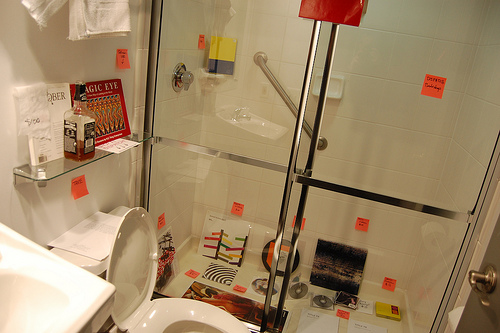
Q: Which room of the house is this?
A: It is a bathroom.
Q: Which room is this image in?
A: It is at the bathroom.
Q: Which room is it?
A: It is a bathroom.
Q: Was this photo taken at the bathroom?
A: Yes, it was taken in the bathroom.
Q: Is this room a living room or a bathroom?
A: It is a bathroom.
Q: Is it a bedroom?
A: No, it is a bathroom.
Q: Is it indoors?
A: Yes, it is indoors.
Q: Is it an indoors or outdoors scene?
A: It is indoors.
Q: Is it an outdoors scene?
A: No, it is indoors.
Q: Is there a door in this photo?
A: Yes, there is a door.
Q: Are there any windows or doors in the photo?
A: Yes, there is a door.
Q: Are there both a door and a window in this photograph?
A: No, there is a door but no windows.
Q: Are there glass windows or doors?
A: Yes, there is a glass door.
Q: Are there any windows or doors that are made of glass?
A: Yes, the door is made of glass.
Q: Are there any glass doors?
A: Yes, there is a door that is made of glass.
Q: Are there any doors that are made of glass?
A: Yes, there is a door that is made of glass.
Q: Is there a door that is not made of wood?
A: Yes, there is a door that is made of glass.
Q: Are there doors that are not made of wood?
A: Yes, there is a door that is made of glass.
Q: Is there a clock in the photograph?
A: No, there are no clocks.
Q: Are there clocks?
A: No, there are no clocks.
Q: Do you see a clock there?
A: No, there are no clocks.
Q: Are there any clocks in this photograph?
A: No, there are no clocks.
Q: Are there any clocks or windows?
A: No, there are no clocks or windows.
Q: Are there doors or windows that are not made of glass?
A: No, there is a door but it is made of glass.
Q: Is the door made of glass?
A: Yes, the door is made of glass.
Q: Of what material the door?
A: The door is made of glass.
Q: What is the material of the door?
A: The door is made of glass.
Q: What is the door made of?
A: The door is made of glass.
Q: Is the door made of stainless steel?
A: No, the door is made of glass.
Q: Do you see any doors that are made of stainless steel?
A: No, there is a door but it is made of glass.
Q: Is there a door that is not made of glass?
A: No, there is a door but it is made of glass.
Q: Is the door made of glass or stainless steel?
A: The door is made of glass.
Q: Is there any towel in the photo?
A: Yes, there is a towel.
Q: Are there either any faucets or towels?
A: Yes, there is a towel.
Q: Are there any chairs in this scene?
A: No, there are no chairs.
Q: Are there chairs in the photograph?
A: No, there are no chairs.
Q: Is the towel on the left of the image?
A: Yes, the towel is on the left of the image.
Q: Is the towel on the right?
A: No, the towel is on the left of the image.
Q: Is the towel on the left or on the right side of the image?
A: The towel is on the left of the image.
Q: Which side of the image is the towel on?
A: The towel is on the left of the image.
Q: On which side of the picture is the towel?
A: The towel is on the left of the image.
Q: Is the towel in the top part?
A: Yes, the towel is in the top of the image.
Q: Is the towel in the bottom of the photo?
A: No, the towel is in the top of the image.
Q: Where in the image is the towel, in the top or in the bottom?
A: The towel is in the top of the image.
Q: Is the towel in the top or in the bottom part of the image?
A: The towel is in the top of the image.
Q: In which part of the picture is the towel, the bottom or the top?
A: The towel is in the top of the image.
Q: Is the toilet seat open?
A: Yes, the toilet seat is open.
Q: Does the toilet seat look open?
A: Yes, the toilet seat is open.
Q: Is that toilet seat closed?
A: No, the toilet seat is open.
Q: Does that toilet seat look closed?
A: No, the toilet seat is open.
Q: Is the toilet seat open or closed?
A: The toilet seat is open.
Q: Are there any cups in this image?
A: No, there are no cups.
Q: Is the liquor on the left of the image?
A: Yes, the liquor is on the left of the image.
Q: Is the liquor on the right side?
A: No, the liquor is on the left of the image.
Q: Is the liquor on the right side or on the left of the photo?
A: The liquor is on the left of the image.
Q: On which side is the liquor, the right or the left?
A: The liquor is on the left of the image.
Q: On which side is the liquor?
A: The liquor is on the left of the image.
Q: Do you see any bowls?
A: No, there are no bowls.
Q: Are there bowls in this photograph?
A: No, there are no bowls.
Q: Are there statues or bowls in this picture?
A: No, there are no bowls or statues.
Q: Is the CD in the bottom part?
A: Yes, the CD is in the bottom of the image.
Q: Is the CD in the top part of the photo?
A: No, the CD is in the bottom of the image.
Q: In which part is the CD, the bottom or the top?
A: The CD is in the bottom of the image.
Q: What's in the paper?
A: The CD is in the paper.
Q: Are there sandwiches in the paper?
A: No, there is a CD in the paper.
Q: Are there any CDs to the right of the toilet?
A: Yes, there is a CD to the right of the toilet.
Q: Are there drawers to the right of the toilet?
A: No, there is a CD to the right of the toilet.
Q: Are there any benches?
A: No, there are no benches.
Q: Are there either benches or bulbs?
A: No, there are no benches or bulbs.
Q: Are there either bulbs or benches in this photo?
A: No, there are no benches or bulbs.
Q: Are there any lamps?
A: No, there are no lamps.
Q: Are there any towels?
A: Yes, there is a towel.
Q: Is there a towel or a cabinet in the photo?
A: Yes, there is a towel.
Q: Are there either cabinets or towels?
A: Yes, there is a towel.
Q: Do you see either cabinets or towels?
A: Yes, there is a towel.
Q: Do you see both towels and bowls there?
A: No, there is a towel but no bowls.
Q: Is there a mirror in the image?
A: No, there are no mirrors.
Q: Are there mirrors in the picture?
A: No, there are no mirrors.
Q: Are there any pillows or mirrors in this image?
A: No, there are no mirrors or pillows.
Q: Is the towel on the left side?
A: Yes, the towel is on the left of the image.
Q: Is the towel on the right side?
A: No, the towel is on the left of the image.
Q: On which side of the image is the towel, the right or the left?
A: The towel is on the left of the image.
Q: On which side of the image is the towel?
A: The towel is on the left of the image.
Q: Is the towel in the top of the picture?
A: Yes, the towel is in the top of the image.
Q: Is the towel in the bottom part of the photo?
A: No, the towel is in the top of the image.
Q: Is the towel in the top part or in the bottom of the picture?
A: The towel is in the top of the image.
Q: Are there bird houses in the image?
A: No, there are no bird houses.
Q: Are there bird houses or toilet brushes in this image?
A: No, there are no bird houses or toilet brushes.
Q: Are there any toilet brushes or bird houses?
A: No, there are no bird houses or toilet brushes.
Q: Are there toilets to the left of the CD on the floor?
A: Yes, there is a toilet to the left of the CD.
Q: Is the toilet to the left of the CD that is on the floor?
A: Yes, the toilet is to the left of the CD.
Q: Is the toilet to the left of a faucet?
A: No, the toilet is to the left of the CD.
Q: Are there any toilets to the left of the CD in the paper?
A: Yes, there is a toilet to the left of the CD.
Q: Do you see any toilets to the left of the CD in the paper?
A: Yes, there is a toilet to the left of the CD.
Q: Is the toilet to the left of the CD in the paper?
A: Yes, the toilet is to the left of the CD.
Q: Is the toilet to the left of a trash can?
A: No, the toilet is to the left of the CD.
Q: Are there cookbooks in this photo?
A: No, there are no cookbooks.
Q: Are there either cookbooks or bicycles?
A: No, there are no cookbooks or bicycles.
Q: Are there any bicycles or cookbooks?
A: No, there are no cookbooks or bicycles.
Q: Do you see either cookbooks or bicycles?
A: No, there are no cookbooks or bicycles.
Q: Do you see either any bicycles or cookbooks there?
A: No, there are no cookbooks or bicycles.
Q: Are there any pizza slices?
A: No, there are no pizza slices.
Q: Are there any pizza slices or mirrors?
A: No, there are no pizza slices or mirrors.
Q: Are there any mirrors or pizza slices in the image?
A: No, there are no pizza slices or mirrors.